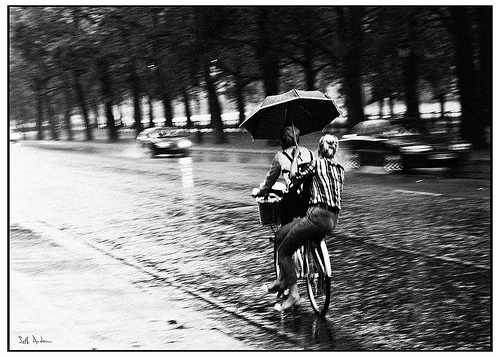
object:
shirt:
[291, 157, 345, 211]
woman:
[267, 134, 344, 310]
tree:
[111, 7, 161, 139]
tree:
[144, 6, 191, 128]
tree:
[185, 0, 242, 142]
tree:
[56, 24, 106, 141]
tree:
[9, 6, 93, 141]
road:
[8, 131, 490, 351]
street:
[111, 147, 234, 323]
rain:
[143, 254, 455, 350]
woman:
[251, 126, 316, 198]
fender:
[320, 239, 332, 278]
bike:
[252, 183, 332, 320]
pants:
[276, 203, 337, 286]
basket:
[256, 198, 283, 226]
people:
[252, 126, 344, 310]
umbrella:
[239, 88, 341, 142]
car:
[136, 126, 192, 158]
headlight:
[154, 141, 170, 148]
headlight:
[178, 140, 192, 148]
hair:
[318, 134, 339, 158]